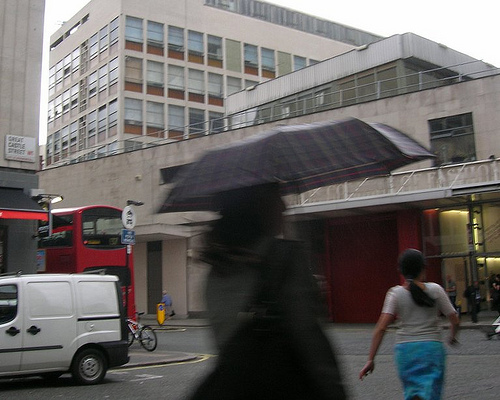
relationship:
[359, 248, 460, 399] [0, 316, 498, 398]
girl on street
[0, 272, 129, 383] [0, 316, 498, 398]
van on street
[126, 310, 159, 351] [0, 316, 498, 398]
bike on street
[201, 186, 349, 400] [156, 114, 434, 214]
lady has umbrella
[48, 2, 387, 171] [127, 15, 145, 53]
building has window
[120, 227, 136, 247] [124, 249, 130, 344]
sign on pole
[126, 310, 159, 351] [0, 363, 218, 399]
bike on street